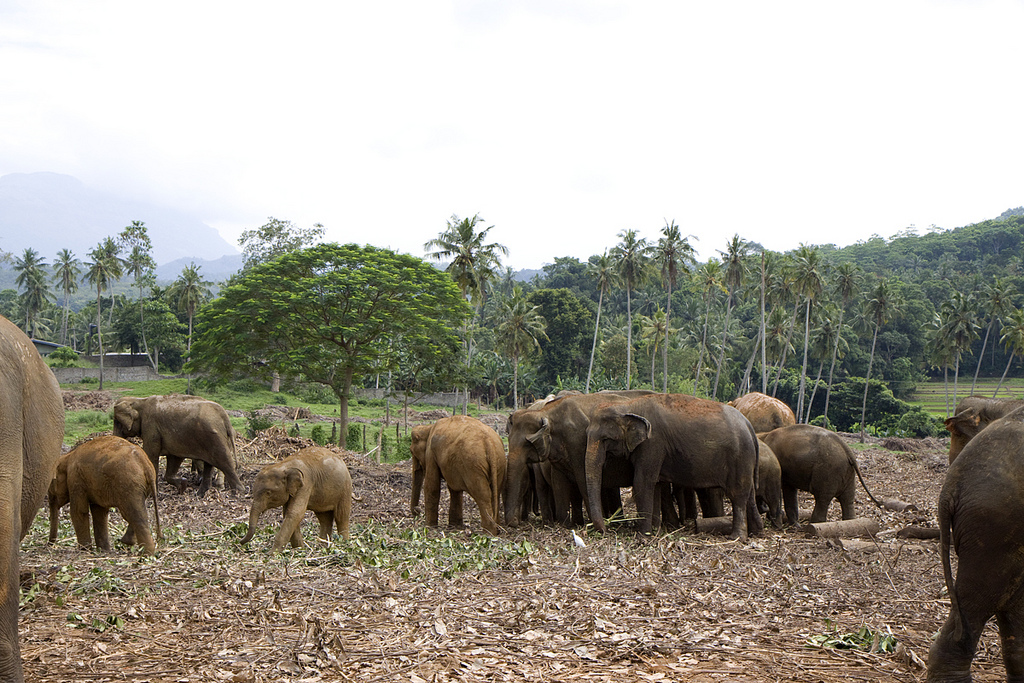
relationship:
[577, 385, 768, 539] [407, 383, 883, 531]
elephant standing in huddle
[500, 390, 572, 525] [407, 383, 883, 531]
elephant standing in huddle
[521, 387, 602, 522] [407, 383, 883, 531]
elephant standing in huddle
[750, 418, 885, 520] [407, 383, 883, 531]
elephant standing in huddle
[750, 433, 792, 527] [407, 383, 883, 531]
elephant standing in huddle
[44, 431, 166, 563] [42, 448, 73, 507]
elephant hanging head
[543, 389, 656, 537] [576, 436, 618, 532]
elephant has trunk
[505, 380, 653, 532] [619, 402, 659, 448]
elephant has ear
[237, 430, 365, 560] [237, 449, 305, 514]
elephant has head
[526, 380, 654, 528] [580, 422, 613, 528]
elephant has trunk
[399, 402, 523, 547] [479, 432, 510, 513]
elephant has tail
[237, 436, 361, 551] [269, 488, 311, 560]
elephant has legs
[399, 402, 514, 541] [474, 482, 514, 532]
elephant has legs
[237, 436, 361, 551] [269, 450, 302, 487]
elephant has ear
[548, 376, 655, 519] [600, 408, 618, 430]
elephant has eye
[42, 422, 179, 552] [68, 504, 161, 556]
elephant has feet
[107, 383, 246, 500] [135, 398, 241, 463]
elephant has body